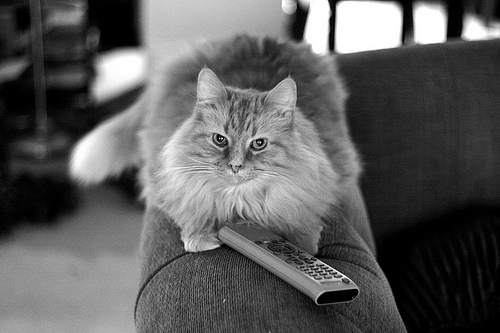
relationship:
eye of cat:
[202, 121, 244, 149] [79, 23, 362, 273]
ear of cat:
[178, 47, 229, 106] [79, 23, 362, 273]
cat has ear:
[79, 23, 362, 273] [178, 47, 229, 106]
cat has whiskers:
[79, 23, 362, 273] [165, 163, 207, 192]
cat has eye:
[79, 23, 362, 273] [202, 121, 244, 149]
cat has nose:
[79, 23, 362, 273] [217, 159, 249, 185]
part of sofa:
[379, 85, 425, 130] [372, 50, 490, 171]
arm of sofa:
[126, 226, 265, 320] [372, 50, 490, 239]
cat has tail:
[79, 23, 362, 273] [49, 89, 151, 209]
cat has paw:
[79, 23, 362, 273] [166, 212, 224, 265]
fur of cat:
[189, 46, 255, 104] [79, 23, 362, 273]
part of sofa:
[379, 85, 425, 130] [372, 50, 490, 239]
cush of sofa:
[404, 205, 453, 277] [372, 50, 490, 239]